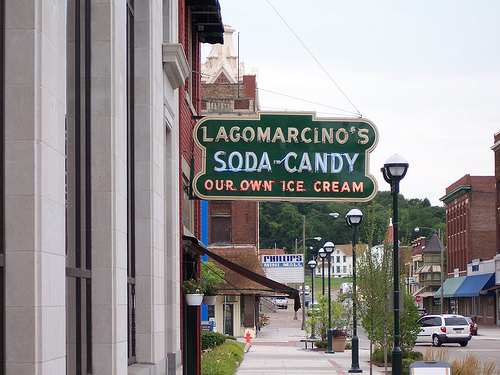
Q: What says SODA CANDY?
A: The sign.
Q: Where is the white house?
A: Down the street.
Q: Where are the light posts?
A: The sidewalk.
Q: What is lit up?
A: Store sign.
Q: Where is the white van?
A: In the street.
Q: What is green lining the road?
A: Small trees.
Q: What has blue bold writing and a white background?
A: PHILLIPS sign.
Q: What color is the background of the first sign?
A: Green.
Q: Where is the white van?
A: On the street.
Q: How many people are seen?
A: None.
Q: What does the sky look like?
A: Overcast.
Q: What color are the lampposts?
A: Black.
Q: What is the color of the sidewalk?
A: Light gray.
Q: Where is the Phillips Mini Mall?
A: On the left side of the road.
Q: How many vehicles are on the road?
A: One.